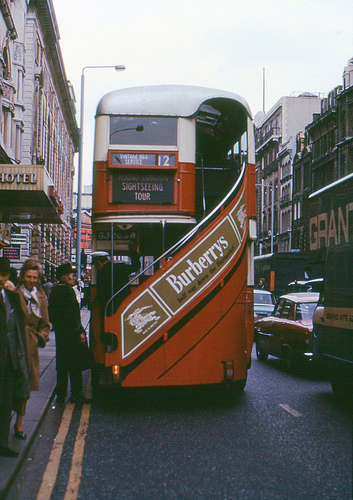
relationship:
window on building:
[0, 104, 11, 149] [0, 1, 84, 319]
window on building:
[275, 163, 288, 242] [233, 90, 329, 323]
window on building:
[266, 180, 272, 206] [276, 134, 296, 254]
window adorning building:
[269, 113, 280, 133] [289, 57, 351, 251]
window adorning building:
[272, 180, 277, 204] [289, 57, 351, 251]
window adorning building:
[257, 155, 265, 168] [289, 57, 351, 251]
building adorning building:
[251, 94, 327, 248] [289, 57, 351, 251]